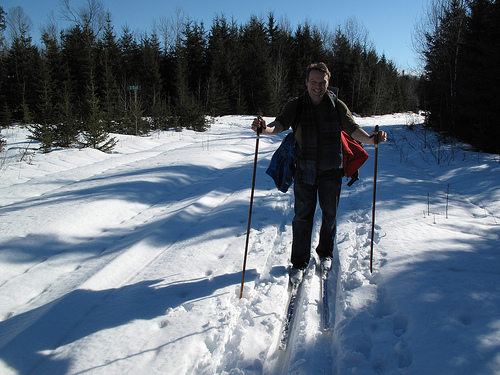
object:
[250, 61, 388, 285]
man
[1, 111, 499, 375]
snow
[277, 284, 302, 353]
skis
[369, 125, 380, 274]
poles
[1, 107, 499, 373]
ground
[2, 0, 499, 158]
trees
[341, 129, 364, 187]
backpack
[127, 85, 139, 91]
sign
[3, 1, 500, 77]
sky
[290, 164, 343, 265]
jeans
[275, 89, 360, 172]
jacket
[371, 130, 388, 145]
hand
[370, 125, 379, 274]
pole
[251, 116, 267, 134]
hand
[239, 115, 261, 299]
pole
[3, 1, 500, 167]
background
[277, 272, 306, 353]
tracks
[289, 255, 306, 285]
boots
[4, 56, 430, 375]
road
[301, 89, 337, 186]
scarf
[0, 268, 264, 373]
shadow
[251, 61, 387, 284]
skier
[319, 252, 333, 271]
feet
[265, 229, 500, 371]
shadows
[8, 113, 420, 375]
trail